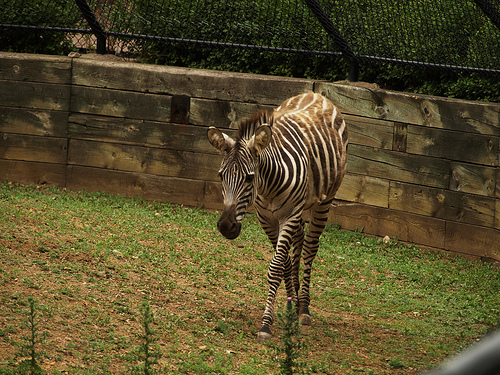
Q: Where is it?
A: Cage.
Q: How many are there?
A: 1.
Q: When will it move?
A: Soon.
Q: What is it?
A: Zebra.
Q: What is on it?
A: Strips.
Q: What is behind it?
A: Wall.